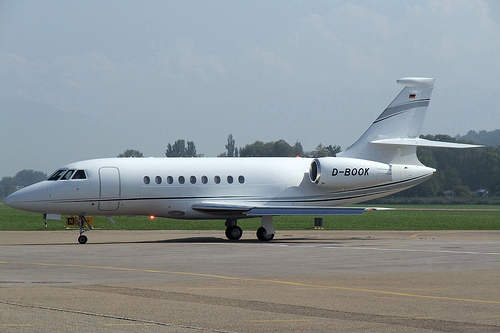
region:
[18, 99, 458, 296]
plane is big and white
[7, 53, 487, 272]
A small jet on the runway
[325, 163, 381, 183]
the name written on the side of the plane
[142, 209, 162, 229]
a red light under the plane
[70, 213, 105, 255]
the front wheel of the plane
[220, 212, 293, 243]
the back wheels of the plane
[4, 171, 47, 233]
the nose of the airplane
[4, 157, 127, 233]
the cockpit of the plane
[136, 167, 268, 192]
small round passenger windows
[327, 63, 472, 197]
the tail of the plane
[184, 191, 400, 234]
the left wing of the plane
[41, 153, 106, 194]
Windshield to a plane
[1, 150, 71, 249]
Nose of a plane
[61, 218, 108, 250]
Front wheels of a plane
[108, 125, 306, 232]
Body of the plane with part of a wing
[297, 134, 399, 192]
D-Book turbo jet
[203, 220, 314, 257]
Back wheels to a plane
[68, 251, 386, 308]
Asphalt/concrete ground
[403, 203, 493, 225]
Some grass behind the plane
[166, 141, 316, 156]
Some trees in the background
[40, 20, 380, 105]
Hazy sky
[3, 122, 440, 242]
jet is white and long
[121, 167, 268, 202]
Windows on an air plane.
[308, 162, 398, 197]
Black letters that say d-book.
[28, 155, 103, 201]
The pilots window on a plane.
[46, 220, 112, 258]
A small wheel of a plane.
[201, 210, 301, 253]
Two black tires on a plane.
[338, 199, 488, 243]
A green ares of grass.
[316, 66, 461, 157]
White and gray tale of an air plane.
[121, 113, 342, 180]
Green trees behind plane.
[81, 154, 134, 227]
White door of a plane.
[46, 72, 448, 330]
Airplane on the cement.